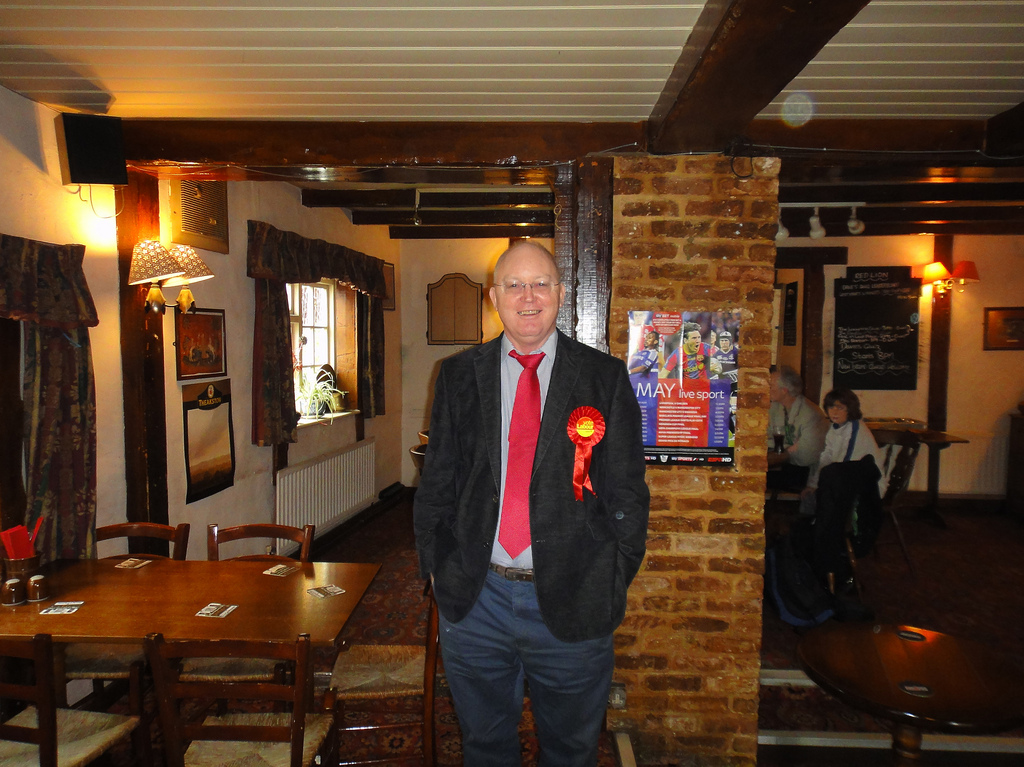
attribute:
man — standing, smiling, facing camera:
[412, 239, 654, 763]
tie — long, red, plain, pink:
[497, 350, 549, 560]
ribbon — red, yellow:
[566, 402, 609, 500]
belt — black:
[484, 559, 536, 584]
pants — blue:
[437, 569, 615, 765]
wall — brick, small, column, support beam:
[604, 153, 785, 765]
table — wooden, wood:
[0, 553, 385, 762]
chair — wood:
[322, 580, 442, 764]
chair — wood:
[142, 630, 344, 765]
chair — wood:
[0, 630, 145, 762]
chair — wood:
[170, 520, 316, 763]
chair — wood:
[54, 519, 193, 765]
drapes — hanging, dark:
[246, 218, 390, 444]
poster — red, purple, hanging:
[627, 309, 744, 465]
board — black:
[834, 279, 924, 390]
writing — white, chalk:
[839, 323, 914, 376]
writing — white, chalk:
[839, 280, 918, 302]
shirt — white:
[814, 417, 889, 487]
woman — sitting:
[800, 386, 889, 591]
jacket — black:
[411, 327, 651, 642]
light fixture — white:
[847, 207, 869, 235]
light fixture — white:
[807, 207, 829, 241]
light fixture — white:
[778, 207, 792, 241]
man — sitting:
[767, 367, 828, 539]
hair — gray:
[776, 365, 806, 399]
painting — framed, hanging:
[175, 305, 230, 382]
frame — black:
[173, 304, 229, 383]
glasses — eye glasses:
[492, 276, 562, 296]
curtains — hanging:
[2, 231, 102, 564]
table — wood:
[796, 615, 1023, 765]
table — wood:
[875, 424, 972, 526]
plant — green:
[297, 366, 345, 426]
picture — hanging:
[181, 376, 238, 506]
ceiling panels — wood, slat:
[1, 1, 710, 123]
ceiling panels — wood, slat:
[750, 0, 1023, 122]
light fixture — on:
[922, 261, 954, 299]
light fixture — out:
[952, 257, 981, 295]